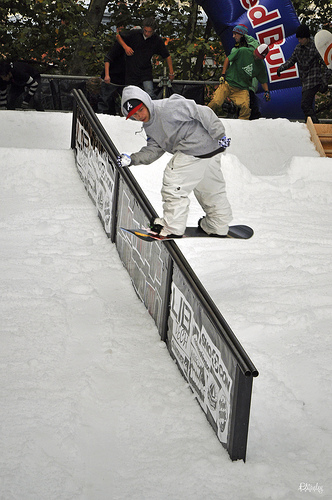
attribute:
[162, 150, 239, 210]
pants — white 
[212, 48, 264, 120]
man — in green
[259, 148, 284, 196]
snow — white 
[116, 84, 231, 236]
man —   snowboarding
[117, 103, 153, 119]
rim hat — red 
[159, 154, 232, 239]
pants —   light  ,   colored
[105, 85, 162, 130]
head —   man's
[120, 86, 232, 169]
jacket — gray